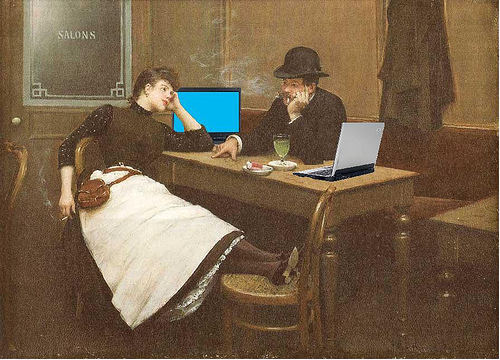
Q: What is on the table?
A: A monitor and laptop computer.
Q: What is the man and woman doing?
A: Taking.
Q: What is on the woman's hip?
A: A purse.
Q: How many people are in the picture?
A: Two.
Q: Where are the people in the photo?
A: Salons.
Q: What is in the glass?
A: A beverage.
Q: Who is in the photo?
A: A man and woman.